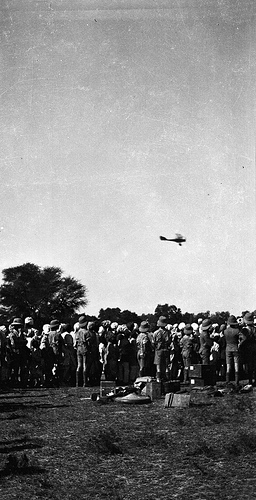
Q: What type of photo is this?
A: Black and white.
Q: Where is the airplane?
A: In the sky.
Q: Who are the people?
A: Observers.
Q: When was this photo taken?
A: In the past.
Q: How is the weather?
A: Cloudy.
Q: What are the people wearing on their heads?
A: Hats.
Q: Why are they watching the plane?
A: It is an airshow.